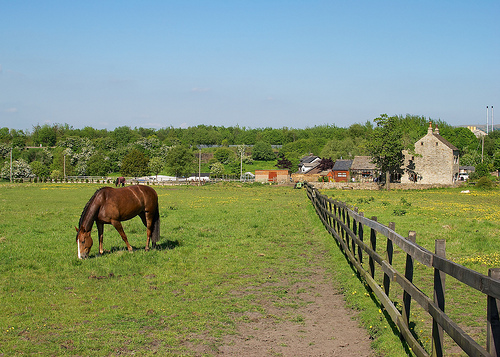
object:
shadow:
[88, 239, 180, 257]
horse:
[73, 183, 165, 262]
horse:
[112, 176, 127, 187]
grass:
[0, 182, 500, 357]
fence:
[299, 180, 500, 357]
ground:
[0, 186, 500, 357]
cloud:
[0, 0, 500, 133]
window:
[336, 171, 347, 178]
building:
[330, 157, 354, 183]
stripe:
[78, 238, 82, 259]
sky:
[0, 0, 500, 132]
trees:
[26, 160, 51, 177]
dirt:
[186, 240, 376, 357]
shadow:
[402, 251, 414, 325]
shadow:
[432, 268, 444, 354]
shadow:
[485, 294, 499, 357]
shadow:
[383, 234, 395, 295]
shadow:
[369, 225, 377, 278]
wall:
[397, 127, 454, 184]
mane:
[78, 188, 100, 229]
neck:
[77, 200, 100, 232]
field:
[0, 185, 500, 357]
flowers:
[255, 198, 260, 202]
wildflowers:
[42, 187, 46, 191]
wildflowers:
[467, 255, 499, 268]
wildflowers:
[221, 201, 226, 204]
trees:
[0, 156, 39, 184]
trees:
[82, 152, 111, 176]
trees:
[163, 144, 198, 179]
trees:
[363, 112, 420, 190]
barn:
[398, 120, 463, 187]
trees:
[118, 142, 159, 178]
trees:
[250, 139, 275, 161]